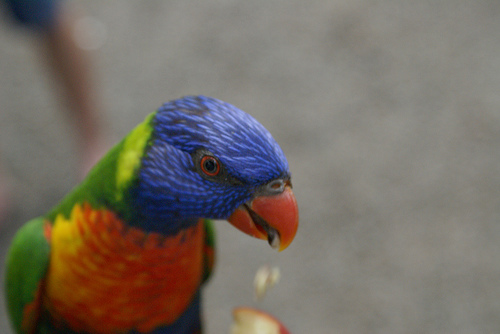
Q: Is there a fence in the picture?
A: No, there are no fences.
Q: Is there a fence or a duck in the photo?
A: No, there are no fences or ducks.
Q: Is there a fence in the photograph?
A: No, there are no fences.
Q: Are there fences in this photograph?
A: No, there are no fences.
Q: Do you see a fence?
A: No, there are no fences.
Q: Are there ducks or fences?
A: No, there are no fences or ducks.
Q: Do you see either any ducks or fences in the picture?
A: No, there are no fences or ducks.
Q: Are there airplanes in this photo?
A: No, there are no airplanes.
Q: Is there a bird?
A: Yes, there is a bird.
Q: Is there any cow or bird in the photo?
A: Yes, there is a bird.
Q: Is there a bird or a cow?
A: Yes, there is a bird.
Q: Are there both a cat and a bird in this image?
A: No, there is a bird but no cats.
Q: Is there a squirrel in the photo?
A: No, there are no squirrels.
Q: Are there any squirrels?
A: No, there are no squirrels.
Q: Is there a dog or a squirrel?
A: No, there are no squirrels or dogs.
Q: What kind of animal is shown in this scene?
A: The animal is a bird.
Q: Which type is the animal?
A: The animal is a bird.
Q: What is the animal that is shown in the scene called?
A: The animal is a bird.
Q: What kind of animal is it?
A: The animal is a bird.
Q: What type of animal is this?
A: This is a bird.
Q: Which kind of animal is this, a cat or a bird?
A: This is a bird.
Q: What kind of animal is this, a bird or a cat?
A: This is a bird.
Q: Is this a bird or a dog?
A: This is a bird.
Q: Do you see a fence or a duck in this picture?
A: No, there are no fences or ducks.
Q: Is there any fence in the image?
A: No, there are no fences.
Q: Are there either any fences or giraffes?
A: No, there are no fences or giraffes.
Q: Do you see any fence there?
A: No, there are no fences.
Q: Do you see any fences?
A: No, there are no fences.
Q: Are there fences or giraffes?
A: No, there are no fences or giraffes.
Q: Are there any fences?
A: No, there are no fences.